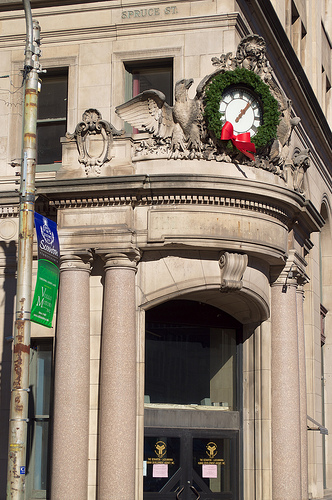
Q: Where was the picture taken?
A: Outside of a bank.